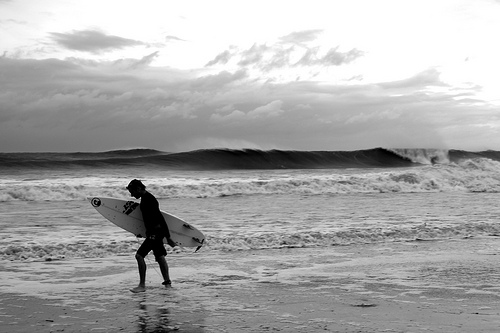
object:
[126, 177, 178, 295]
man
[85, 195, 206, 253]
surfboard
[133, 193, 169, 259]
wetsuit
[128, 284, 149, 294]
wet feet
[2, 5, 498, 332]
picture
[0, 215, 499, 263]
waves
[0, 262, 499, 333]
shore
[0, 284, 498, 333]
sand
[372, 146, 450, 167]
wave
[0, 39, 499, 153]
mist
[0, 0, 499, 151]
clouds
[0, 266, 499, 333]
beach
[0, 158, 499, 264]
surf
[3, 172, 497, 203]
foam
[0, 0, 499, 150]
sky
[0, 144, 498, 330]
water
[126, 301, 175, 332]
reflection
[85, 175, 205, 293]
surfing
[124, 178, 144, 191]
hat